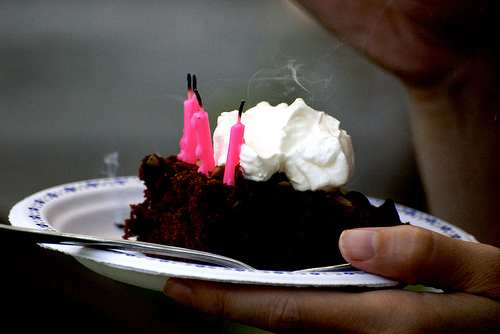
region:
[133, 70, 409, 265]
Chocolate cake with pink candles topped with whipped cream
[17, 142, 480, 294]
Chocolate cake on a paper plate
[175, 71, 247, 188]
Half burnt pink candles on a cake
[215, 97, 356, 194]
Whipped cream behind a pink candle on a cake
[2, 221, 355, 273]
Fork on a paper plate with cake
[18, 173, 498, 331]
Paper plate with cake being held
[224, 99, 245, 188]
a pink birthday candle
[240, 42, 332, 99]
smoke from an extinguished candle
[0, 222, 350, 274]
a metal dinner fork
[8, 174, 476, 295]
a white and blue paper plate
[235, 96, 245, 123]
the burnt wick of the candle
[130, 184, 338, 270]
a slice of chocolate cake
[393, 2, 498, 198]
the raised arm of a person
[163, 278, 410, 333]
the forefinger of a nicotine stained hand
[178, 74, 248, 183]
four blown out candles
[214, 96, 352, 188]
a spoon of whip cream on the top of cake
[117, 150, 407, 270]
a slice of chocolate cake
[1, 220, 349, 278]
silver utensil on the side of plate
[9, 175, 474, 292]
a white plate with cake on it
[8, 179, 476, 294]
a white, paper plate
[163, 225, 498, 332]
part of hand holding cake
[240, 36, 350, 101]
smoke rising from candle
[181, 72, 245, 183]
four pink blown out candles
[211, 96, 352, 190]
white fluffy whipped cream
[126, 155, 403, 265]
slice of chocolate cake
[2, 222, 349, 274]
silver metal form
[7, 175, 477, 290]
blue and white plate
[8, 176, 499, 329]
hand holding plate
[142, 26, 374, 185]
smoke from the blown out candles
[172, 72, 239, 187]
melted wax on the candles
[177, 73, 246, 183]
candles are pink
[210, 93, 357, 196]
whipped cream is white and fluffy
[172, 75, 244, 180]
Bright pink candles on a piece of cake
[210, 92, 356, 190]
Whipped cream on a slice of cake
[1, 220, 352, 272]
A silver fork on a plate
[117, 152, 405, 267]
A piece of brown cake on a plate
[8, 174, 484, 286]
A paper plate under a piece of cake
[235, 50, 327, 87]
Smoke wafting from birthday candles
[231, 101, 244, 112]
Burnt string on a candle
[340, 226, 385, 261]
A fingernail on a thumb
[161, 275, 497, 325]
An index finger on a hand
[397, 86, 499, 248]
A person's neck near a plate with cake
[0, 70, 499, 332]
person holding a plate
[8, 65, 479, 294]
cake slice on a plate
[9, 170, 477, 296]
plate is white and blue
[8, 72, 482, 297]
chocolate cake on plate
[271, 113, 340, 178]
cream on the cake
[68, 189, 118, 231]
a paper plate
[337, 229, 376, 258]
a persons nail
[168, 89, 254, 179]
pink candles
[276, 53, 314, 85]
smoke in the air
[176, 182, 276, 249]
a chocolate cake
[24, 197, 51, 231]
a design on the plate